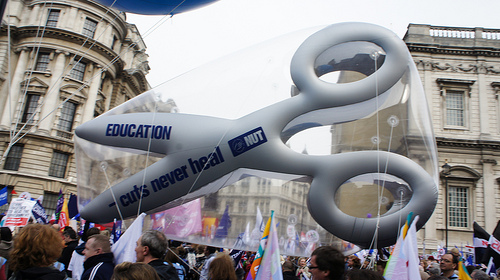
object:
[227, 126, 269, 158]
logo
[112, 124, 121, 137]
d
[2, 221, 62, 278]
hair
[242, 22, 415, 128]
handle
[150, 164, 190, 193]
word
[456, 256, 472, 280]
flag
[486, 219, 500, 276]
flags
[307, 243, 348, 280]
man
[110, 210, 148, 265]
flag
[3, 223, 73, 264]
head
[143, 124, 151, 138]
letter 't'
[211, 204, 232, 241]
flags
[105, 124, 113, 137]
letter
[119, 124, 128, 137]
letter u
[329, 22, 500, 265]
building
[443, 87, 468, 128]
window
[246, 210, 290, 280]
flag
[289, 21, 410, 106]
shape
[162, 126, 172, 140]
letter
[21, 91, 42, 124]
window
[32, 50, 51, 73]
window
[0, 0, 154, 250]
building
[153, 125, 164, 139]
letter o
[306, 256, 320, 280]
shades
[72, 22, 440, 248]
inflatable scissors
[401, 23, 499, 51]
parapet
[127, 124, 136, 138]
letter c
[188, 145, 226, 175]
word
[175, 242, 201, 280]
people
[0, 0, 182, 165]
string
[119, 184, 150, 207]
cuts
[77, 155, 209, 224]
blade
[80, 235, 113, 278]
man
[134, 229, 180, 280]
man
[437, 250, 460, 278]
man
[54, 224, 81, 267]
man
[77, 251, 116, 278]
jacket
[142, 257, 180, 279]
jacket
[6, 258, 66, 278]
jacket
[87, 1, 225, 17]
balloon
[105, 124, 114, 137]
letter e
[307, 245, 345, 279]
face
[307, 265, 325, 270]
sunglasses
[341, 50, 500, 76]
roof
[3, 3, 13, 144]
string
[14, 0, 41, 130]
string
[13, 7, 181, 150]
string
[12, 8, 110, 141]
string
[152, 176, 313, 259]
paper